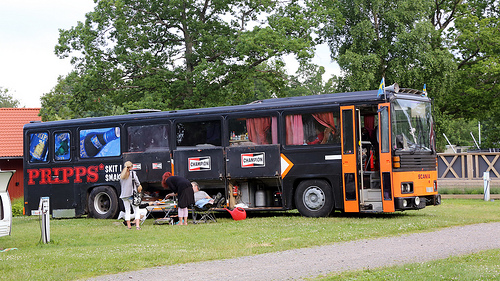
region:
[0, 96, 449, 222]
orange and black bus with advertising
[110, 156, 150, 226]
woman standing near bus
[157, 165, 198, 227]
person with white pants and black shirt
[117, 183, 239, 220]
two people on lounge chairs near bus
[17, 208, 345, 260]
green grassy area next to bus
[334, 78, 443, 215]
orange and black front end of bus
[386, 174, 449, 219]
lighting on front end of bus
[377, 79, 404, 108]
horn mounted on top front corner of bus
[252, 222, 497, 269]
gray gravel pathway in front of bus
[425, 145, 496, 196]
tan and black fencing next to bus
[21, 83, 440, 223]
A black and orange bus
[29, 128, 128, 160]
Beer bottle advertisements in the window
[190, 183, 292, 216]
Two open luggage compartments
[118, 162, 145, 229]
A woman wears a black purse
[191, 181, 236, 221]
Woman lounges in a chair on the ground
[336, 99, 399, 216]
The doors of the bus are open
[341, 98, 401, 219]
The doors of the bus are orange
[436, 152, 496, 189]
The fence has wooden x's on it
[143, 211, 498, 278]
A gravel driveway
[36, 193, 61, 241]
An electrical outlet stand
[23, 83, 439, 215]
A dark colored bus.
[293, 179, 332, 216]
A front wheel of a bus.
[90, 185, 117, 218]
A rear wheel of a bus.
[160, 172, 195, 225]
A female with a red hair.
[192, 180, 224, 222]
A person on a chair.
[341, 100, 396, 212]
A door on a bus.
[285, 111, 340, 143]
Red curtains on a bus.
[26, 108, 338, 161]
Windows on a bus.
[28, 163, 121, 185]
A sign on a bus.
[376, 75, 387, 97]
A blue flag.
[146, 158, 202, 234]
this is a person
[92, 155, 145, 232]
this is a person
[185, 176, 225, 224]
this is a person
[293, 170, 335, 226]
this is a wheel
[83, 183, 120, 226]
this is a wheel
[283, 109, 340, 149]
this is a window of a bus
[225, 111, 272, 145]
this is a window of a bus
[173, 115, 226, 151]
this is a window of a bus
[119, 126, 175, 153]
this is a window of a bus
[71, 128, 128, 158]
this is a window of a bus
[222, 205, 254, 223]
red watering can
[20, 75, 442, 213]
black and orange bus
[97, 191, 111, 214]
missing hubcap off tire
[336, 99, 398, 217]
orange doors on the bus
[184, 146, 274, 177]
two champion spark plug logos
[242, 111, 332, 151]
red curtains in the window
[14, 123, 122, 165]
drink decals on the back windows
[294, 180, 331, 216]
big tires for the bus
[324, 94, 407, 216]
the doors on the bus are open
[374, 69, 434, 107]
there are two flags on top of the bus